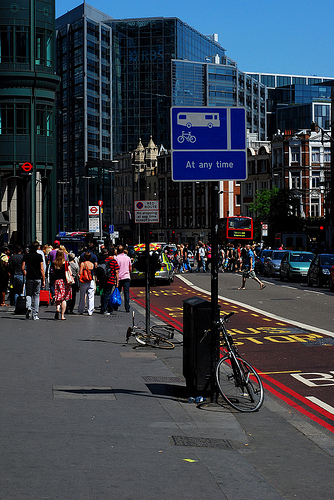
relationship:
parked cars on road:
[307, 254, 333, 286] [133, 256, 329, 430]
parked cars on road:
[279, 244, 309, 281] [133, 256, 329, 430]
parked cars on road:
[265, 245, 280, 276] [133, 256, 329, 430]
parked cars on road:
[259, 248, 265, 269] [133, 256, 329, 430]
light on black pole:
[145, 133, 157, 171] [143, 223, 152, 337]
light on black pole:
[132, 135, 147, 174] [143, 223, 152, 337]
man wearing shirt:
[115, 245, 133, 312] [107, 248, 134, 285]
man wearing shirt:
[105, 247, 140, 302] [101, 257, 121, 286]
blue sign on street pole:
[171, 106, 247, 181] [208, 177, 222, 400]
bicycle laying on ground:
[126, 310, 175, 350] [1, 271, 333, 498]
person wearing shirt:
[22, 241, 46, 320] [21, 251, 46, 279]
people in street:
[166, 239, 265, 278] [174, 242, 332, 338]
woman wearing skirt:
[49, 244, 72, 318] [49, 246, 72, 320]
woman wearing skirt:
[52, 249, 75, 320] [52, 279, 72, 301]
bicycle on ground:
[123, 309, 175, 349] [1, 271, 333, 498]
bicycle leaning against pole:
[200, 311, 265, 413] [206, 180, 221, 397]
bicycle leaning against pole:
[194, 312, 272, 408] [198, 93, 241, 399]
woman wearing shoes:
[52, 249, 75, 320] [53, 310, 65, 321]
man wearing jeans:
[8, 246, 28, 286] [25, 279, 41, 316]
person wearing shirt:
[98, 246, 119, 315] [104, 256, 119, 283]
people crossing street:
[162, 237, 279, 291] [248, 290, 320, 327]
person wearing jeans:
[17, 239, 47, 323] [23, 274, 41, 319]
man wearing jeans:
[115, 245, 133, 312] [115, 275, 132, 312]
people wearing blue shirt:
[238, 245, 264, 290] [244, 247, 255, 267]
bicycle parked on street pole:
[200, 311, 265, 413] [208, 177, 222, 400]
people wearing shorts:
[238, 245, 264, 290] [242, 265, 255, 277]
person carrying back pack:
[98, 246, 119, 315] [95, 259, 113, 285]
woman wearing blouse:
[52, 249, 75, 320] [49, 259, 69, 283]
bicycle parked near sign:
[200, 311, 265, 413] [168, 104, 248, 181]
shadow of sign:
[49, 381, 195, 404] [168, 104, 248, 181]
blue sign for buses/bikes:
[170, 106, 248, 182] [173, 109, 224, 144]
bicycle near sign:
[126, 310, 175, 350] [131, 197, 163, 232]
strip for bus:
[123, 270, 323, 425] [215, 211, 255, 254]